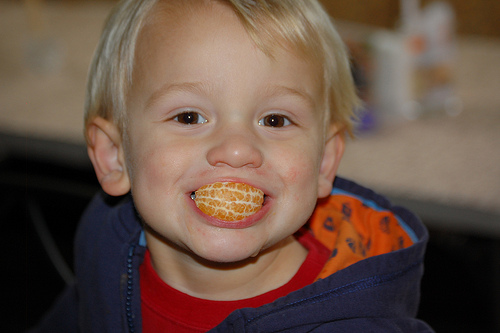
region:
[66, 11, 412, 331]
toddler with a orange slice in his mouth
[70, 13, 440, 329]
toddler is wearing a hoodie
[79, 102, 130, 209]
ear of the toddler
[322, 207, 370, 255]
orange part of the hoodie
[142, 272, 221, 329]
neck of the red shirt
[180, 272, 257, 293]
neck of the boy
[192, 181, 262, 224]
orange slice in the mouth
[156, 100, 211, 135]
brown eye on the kid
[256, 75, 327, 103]
blonde eyebrow on the boy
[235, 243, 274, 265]
dribble on the chin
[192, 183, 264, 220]
An orange in the boy's mouth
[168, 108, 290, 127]
The eyes of the boy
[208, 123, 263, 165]
The nose of the boy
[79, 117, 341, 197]
The ears of the boy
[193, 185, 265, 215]
A slice of an orange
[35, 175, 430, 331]
The boy is wearing a blue sweatshirt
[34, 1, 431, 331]
A boy eating an orange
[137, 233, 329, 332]
A red shirt under the sweatshirt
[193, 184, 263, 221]
An orange fruit in the boy's mouth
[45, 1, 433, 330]
The boy is eating a fruit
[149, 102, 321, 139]
the boy has eyes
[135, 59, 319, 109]
the boy has eyebrows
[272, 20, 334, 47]
the boy has hair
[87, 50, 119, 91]
the hair is blonde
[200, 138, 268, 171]
the boy has a nose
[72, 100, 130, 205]
the boy has a left ear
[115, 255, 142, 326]
the hoodie has a zipper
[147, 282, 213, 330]
the shirt is red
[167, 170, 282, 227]
the orange is in the boys mouth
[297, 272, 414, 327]
the hoodie is purple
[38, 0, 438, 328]
the toddler is blonde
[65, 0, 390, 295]
toddler is eating a tangerine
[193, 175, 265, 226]
a slice of tangerine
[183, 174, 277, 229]
tangerine in the mouth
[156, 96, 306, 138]
the eyes are brown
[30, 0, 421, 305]
boy has short hair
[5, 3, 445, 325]
boy wears a blue jacket with hood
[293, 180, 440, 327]
a hood color blue and orange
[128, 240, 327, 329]
a red top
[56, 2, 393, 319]
a happy smiling toddler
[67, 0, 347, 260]
a child with a tangerine in his mouth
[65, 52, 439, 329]
a child wearing a blue hoodie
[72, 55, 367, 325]
a child wearing a red t-shirt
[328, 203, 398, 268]
orange patterned inseam of the hoodie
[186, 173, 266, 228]
a tangerine in a child's mouth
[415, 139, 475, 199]
grey surface of a table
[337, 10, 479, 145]
several items on the table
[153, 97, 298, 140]
the child's brown eyes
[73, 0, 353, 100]
the child's short blonde hair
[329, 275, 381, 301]
dark blue stitching of the hoodie